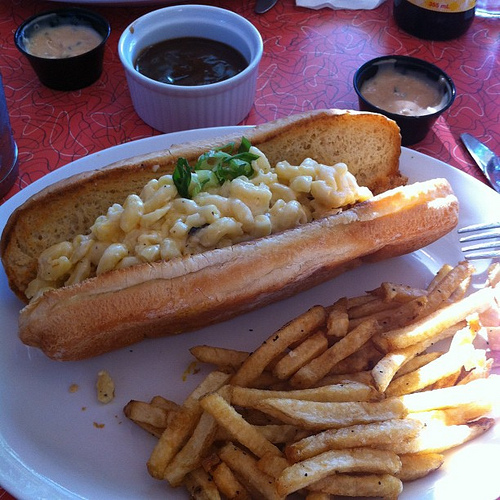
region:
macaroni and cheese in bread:
[262, 197, 294, 212]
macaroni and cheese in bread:
[134, 242, 166, 262]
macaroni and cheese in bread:
[202, 187, 233, 211]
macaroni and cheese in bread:
[124, 230, 156, 252]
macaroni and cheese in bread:
[150, 220, 186, 247]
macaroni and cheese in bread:
[296, 173, 329, 200]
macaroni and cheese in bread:
[260, 195, 299, 220]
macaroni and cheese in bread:
[179, 201, 209, 221]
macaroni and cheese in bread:
[157, 175, 194, 200]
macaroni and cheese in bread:
[202, 230, 226, 246]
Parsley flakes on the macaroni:
[161, 123, 261, 201]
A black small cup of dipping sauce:
[11, 5, 112, 95]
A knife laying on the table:
[455, 125, 499, 196]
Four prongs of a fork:
[456, 215, 499, 265]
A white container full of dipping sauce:
[118, 0, 267, 135]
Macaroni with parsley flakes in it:
[33, 140, 375, 288]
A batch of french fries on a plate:
[145, 339, 463, 489]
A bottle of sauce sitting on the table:
[389, 0, 484, 50]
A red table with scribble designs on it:
[277, 18, 348, 98]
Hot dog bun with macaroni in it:
[8, 100, 464, 359]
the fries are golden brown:
[272, 334, 315, 358]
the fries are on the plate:
[113, 413, 178, 485]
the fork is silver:
[463, 220, 496, 265]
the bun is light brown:
[61, 304, 109, 328]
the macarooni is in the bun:
[99, 183, 155, 230]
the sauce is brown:
[174, 50, 207, 73]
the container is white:
[203, 96, 235, 116]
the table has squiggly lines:
[288, 50, 340, 99]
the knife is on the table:
[456, 133, 493, 168]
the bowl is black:
[49, 68, 75, 83]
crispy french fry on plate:
[271, 424, 401, 498]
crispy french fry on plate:
[260, 378, 498, 417]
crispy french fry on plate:
[397, 327, 492, 394]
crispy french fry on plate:
[367, 349, 418, 404]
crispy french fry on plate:
[382, 278, 494, 358]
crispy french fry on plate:
[330, 291, 347, 337]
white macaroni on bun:
[131, 145, 247, 313]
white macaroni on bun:
[6, 171, 146, 351]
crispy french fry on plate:
[118, 392, 168, 430]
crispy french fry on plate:
[185, 338, 250, 368]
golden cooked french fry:
[280, 448, 400, 493]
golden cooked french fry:
[315, 468, 403, 497]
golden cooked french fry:
[290, 418, 422, 458]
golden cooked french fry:
[258, 395, 405, 425]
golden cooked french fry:
[228, 383, 365, 401]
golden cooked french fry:
[198, 389, 270, 450]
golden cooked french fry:
[219, 442, 276, 494]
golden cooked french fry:
[209, 463, 246, 499]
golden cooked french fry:
[165, 411, 220, 483]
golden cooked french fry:
[295, 318, 377, 382]